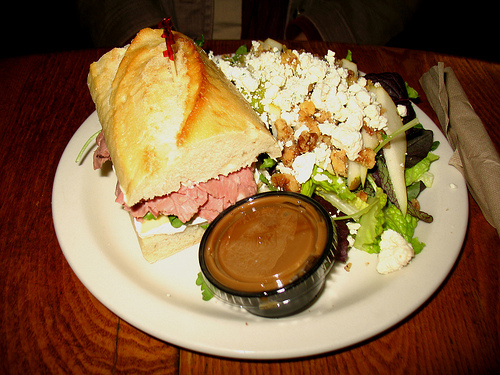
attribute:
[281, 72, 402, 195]
cheese — is crumbled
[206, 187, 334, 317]
container — black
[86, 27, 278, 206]
bun — brown, white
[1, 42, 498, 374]
table — wooden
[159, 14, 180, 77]
toothpick — red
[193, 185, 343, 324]
gravy — brown